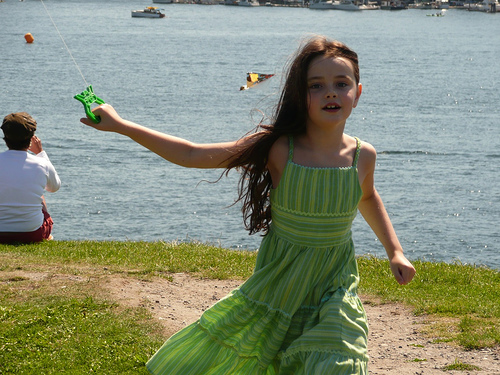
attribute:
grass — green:
[6, 295, 190, 373]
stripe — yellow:
[320, 169, 339, 212]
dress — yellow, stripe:
[144, 134, 370, 373]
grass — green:
[421, 266, 475, 332]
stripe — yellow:
[264, 216, 349, 238]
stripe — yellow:
[328, 173, 340, 204]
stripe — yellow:
[192, 290, 224, 347]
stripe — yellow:
[332, 168, 344, 215]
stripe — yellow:
[234, 287, 295, 373]